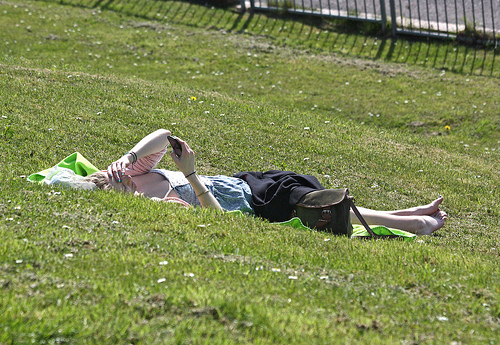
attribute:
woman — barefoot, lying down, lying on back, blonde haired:
[44, 118, 452, 255]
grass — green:
[3, 0, 498, 343]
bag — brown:
[284, 184, 400, 241]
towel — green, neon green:
[26, 147, 418, 244]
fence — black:
[245, 0, 498, 48]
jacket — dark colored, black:
[233, 167, 328, 228]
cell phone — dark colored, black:
[165, 135, 184, 161]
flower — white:
[303, 124, 312, 138]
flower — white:
[92, 109, 107, 122]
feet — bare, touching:
[409, 196, 449, 242]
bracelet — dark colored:
[195, 188, 215, 202]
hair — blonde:
[53, 167, 116, 197]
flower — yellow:
[185, 94, 201, 107]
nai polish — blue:
[111, 174, 126, 183]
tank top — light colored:
[140, 163, 256, 217]